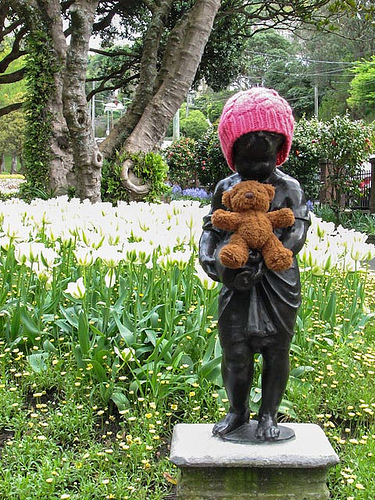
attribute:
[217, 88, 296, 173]
beanie — pink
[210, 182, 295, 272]
stuffed animal — bear, brown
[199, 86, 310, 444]
statue — black, concrete, child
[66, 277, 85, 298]
flower petal — white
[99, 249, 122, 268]
flower petal — white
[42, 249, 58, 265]
flower petal — white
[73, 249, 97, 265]
flower petal — white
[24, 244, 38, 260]
flower petal — white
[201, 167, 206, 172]
rose — red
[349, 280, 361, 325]
stem — green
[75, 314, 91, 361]
stem — green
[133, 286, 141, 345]
stem — green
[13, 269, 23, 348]
stem — green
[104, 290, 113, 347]
stem — green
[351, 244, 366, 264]
daisy — yellow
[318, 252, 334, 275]
daisy — yellow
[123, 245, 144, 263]
daisy — yellow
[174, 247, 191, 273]
daisy — yellow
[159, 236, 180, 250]
daisy — yellow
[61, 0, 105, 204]
tree — tall, huge, large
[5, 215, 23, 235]
flowers — yellow, white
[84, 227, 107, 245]
flowers — y, white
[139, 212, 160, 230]
flowers — yellow, white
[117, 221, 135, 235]
flowers — yellow, white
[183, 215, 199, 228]
flowers — yellow, white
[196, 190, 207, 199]
flower — blue, small, light purple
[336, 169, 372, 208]
fence — metal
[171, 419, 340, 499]
pedestal — concrete, stone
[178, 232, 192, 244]
flower — small, white